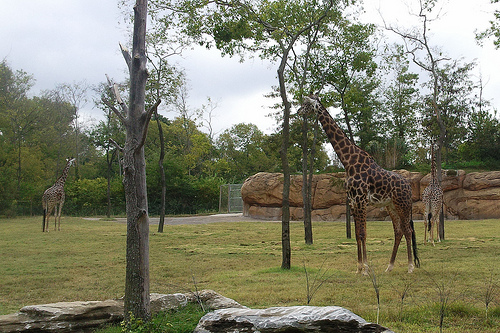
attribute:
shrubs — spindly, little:
[281, 245, 499, 331]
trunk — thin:
[253, 20, 318, 269]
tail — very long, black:
[406, 193, 425, 270]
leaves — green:
[179, 0, 364, 62]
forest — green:
[2, 54, 367, 291]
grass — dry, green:
[0, 215, 499, 331]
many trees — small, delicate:
[8, 37, 490, 282]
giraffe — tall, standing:
[290, 93, 420, 277]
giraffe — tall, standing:
[420, 137, 444, 245]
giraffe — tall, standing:
[38, 154, 75, 234]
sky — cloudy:
[0, 0, 499, 155]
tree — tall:
[143, 0, 351, 274]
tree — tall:
[379, 0, 461, 241]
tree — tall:
[118, 11, 199, 236]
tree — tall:
[40, 75, 95, 218]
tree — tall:
[0, 59, 51, 217]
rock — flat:
[0, 288, 188, 331]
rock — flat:
[185, 303, 392, 332]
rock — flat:
[148, 289, 256, 323]